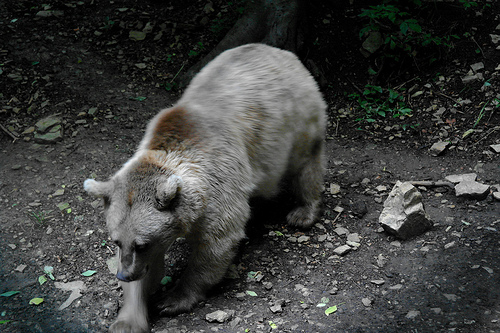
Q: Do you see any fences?
A: No, there are no fences.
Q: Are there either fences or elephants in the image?
A: No, there are no fences or elephants.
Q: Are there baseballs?
A: No, there are no baseballs.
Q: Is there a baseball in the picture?
A: No, there are no baseballs.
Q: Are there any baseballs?
A: No, there are no baseballs.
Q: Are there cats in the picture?
A: No, there are no cats.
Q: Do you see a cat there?
A: No, there are no cats.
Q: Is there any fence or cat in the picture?
A: No, there are no cats or fences.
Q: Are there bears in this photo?
A: Yes, there is a bear.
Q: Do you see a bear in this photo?
A: Yes, there is a bear.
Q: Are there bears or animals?
A: Yes, there is a bear.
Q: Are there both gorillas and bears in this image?
A: No, there is a bear but no gorillas.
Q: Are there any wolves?
A: No, there are no wolves.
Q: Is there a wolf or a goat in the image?
A: No, there are no wolves or goats.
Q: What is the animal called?
A: The animal is a bear.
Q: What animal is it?
A: The animal is a bear.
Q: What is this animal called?
A: This is a bear.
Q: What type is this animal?
A: This is a bear.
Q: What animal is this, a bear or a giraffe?
A: This is a bear.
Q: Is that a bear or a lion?
A: That is a bear.